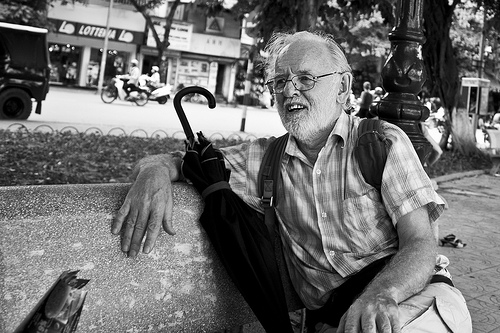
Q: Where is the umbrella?
A: On the bench.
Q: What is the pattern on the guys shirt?
A: Checkered.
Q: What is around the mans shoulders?
A: Backpack.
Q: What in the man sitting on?
A: Bench.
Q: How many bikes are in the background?
A: Two.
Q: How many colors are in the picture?
A: Two.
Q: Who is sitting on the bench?
A: The man.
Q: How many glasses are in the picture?
A: One.